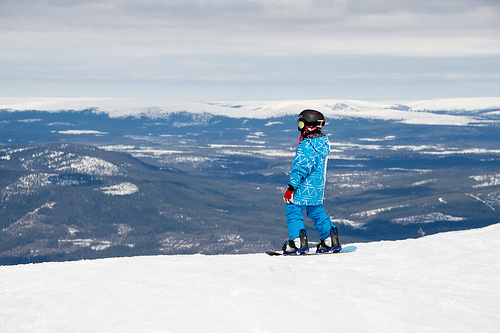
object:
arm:
[279, 143, 318, 203]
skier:
[282, 107, 336, 259]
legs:
[285, 203, 311, 252]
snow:
[0, 82, 498, 117]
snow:
[47, 147, 114, 181]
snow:
[95, 175, 142, 196]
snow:
[393, 139, 498, 157]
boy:
[280, 104, 340, 255]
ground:
[2, 218, 498, 333]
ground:
[394, 106, 446, 143]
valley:
[0, 79, 493, 241]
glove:
[282, 187, 294, 204]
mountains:
[0, 92, 498, 260]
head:
[292, 109, 322, 126]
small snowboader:
[270, 106, 352, 258]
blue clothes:
[281, 137, 332, 208]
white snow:
[0, 220, 499, 332]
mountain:
[0, 217, 497, 331]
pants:
[279, 192, 332, 239]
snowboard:
[261, 244, 359, 257]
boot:
[282, 233, 307, 251]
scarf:
[298, 131, 330, 139]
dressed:
[0, 92, 500, 250]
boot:
[317, 234, 334, 251]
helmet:
[299, 105, 324, 135]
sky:
[0, 0, 499, 104]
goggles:
[296, 117, 313, 129]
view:
[0, 10, 500, 333]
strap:
[303, 130, 316, 138]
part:
[271, 261, 331, 309]